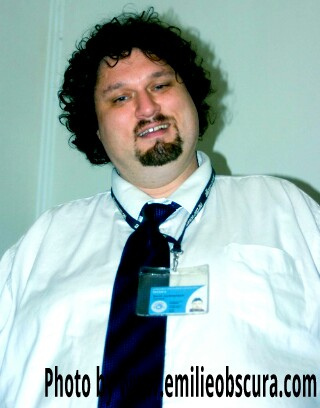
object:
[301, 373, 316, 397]
letter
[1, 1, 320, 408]
picture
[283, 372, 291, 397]
letter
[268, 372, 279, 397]
letter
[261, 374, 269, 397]
letter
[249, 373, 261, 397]
letter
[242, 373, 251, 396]
letter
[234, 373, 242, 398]
letter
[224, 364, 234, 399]
letter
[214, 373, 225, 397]
letter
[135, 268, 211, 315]
badge holder